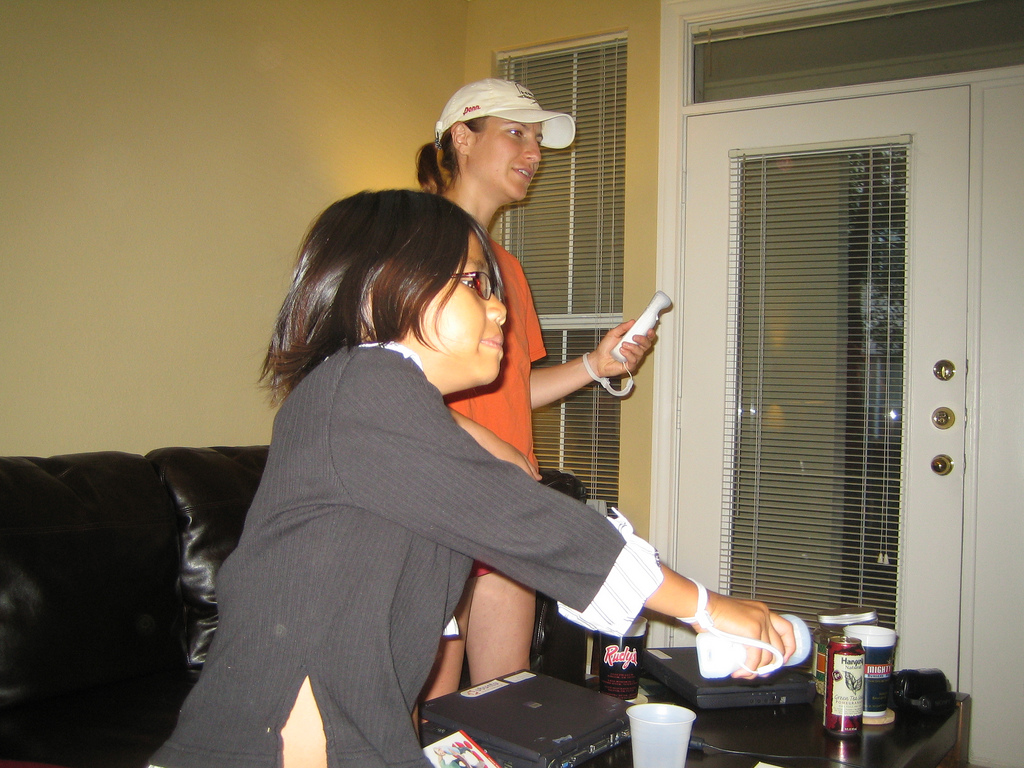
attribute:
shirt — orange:
[427, 218, 570, 501]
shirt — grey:
[190, 324, 843, 717]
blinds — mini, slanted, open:
[720, 143, 917, 687]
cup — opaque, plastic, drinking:
[616, 686, 717, 766]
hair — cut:
[282, 167, 489, 376]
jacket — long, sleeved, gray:
[155, 348, 631, 758]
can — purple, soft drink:
[820, 628, 878, 755]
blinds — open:
[467, 15, 651, 560]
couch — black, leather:
[0, 453, 592, 752]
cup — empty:
[622, 696, 696, 764]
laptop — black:
[632, 630, 809, 710]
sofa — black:
[0, 442, 589, 763]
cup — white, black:
[591, 603, 643, 702]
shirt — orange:
[443, 230, 549, 479]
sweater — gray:
[145, 349, 614, 764]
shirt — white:
[347, 336, 665, 641]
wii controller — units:
[691, 615, 821, 689]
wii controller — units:
[611, 273, 676, 366]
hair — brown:
[263, 191, 519, 403]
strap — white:
[682, 560, 812, 688]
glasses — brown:
[438, 267, 506, 294]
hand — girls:
[695, 593, 799, 687]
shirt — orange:
[449, 219, 538, 474]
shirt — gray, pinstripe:
[113, 338, 667, 766]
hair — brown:
[246, 177, 510, 391]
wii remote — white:
[683, 606, 822, 680]